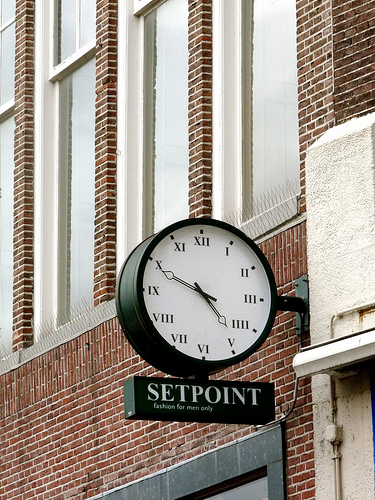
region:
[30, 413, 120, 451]
building made of bricks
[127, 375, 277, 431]
dark green sign that reads setpoint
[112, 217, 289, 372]
dark green clock attached to building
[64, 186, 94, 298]
window on the building made of bricks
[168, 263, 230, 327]
hands on the face of clock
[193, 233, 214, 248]
12 in roman numerals on clock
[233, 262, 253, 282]
2 in roman numerals on clock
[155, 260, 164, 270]
10 in roman numerals on clock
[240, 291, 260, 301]
3 in roman numerals on clock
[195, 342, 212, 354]
6 in roman numerals on clock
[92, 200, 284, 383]
clock hanging on wall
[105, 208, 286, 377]
clock frame is black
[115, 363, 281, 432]
sign hanging under clock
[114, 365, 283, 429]
sign under clock is black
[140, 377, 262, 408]
large letters read setpoint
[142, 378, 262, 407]
setpoint is white letters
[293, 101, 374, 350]
concrete above door jam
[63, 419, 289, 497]
top of door frame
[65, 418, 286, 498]
door frame is black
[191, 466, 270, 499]
glass pane in door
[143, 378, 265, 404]
The word Setpoint below the clock.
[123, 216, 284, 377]
The clock mounted on the side of the brick building.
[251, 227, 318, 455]
The area of the brick wall the clock is mounted on.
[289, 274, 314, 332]
The slab of metal the clock is mounted to.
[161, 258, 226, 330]
The hands of the clock.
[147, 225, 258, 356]
The Roman numerals on the face of the clock.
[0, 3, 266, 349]
The windows on the brick building.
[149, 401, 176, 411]
The word fashion on the sign below the clock.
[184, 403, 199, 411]
The word men on the sign below the clock.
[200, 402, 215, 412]
The word only on the sign below the clock.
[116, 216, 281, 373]
A black clock with a white face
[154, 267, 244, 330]
The time is 4:50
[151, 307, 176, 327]
The roman numeral 8 in black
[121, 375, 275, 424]
A black sign with white letters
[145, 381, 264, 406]
White letters that say "setpoint"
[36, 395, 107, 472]
Red bricks on the building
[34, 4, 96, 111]
Windows with white window sill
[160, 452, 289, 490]
Black slate door trim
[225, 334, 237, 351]
The roman numeral 5 in black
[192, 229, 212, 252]
The roamn numeral 12 in black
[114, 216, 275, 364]
a clock on the side of a building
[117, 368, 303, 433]
a sign that says setpoint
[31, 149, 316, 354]
windows on the front of a building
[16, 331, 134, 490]
bricks on the front of a building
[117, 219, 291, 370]
a clock attached on a building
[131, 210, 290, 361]
a clock that reads four fifty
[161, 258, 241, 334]
clock hands that tells time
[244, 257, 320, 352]
a bracket that attaches a clock to a building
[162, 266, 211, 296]
long hand on a clock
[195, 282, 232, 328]
a short hand on a clock